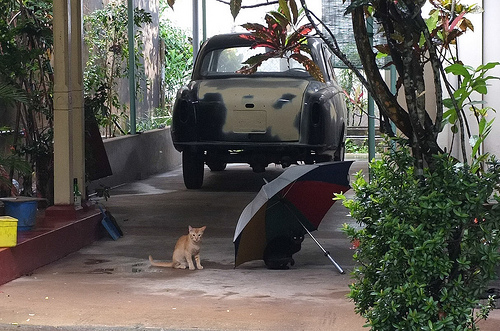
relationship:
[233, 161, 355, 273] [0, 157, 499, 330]
umbrella on top of ground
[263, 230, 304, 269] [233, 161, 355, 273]
cat underneath umbrella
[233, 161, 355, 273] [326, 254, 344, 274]
umbrella has handle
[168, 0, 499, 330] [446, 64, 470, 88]
plant has leaf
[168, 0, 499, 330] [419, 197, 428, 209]
plant has leaf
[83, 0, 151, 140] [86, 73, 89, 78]
plant has leaf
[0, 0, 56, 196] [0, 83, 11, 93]
plant has leaf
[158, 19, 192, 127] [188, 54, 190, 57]
plant has leaf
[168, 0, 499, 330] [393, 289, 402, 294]
plant has leaf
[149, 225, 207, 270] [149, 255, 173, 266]
cat has tail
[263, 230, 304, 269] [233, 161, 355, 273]
fire underneath umbrella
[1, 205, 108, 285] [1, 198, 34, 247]
ledge has buckets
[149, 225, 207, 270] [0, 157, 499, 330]
kitten on top of ground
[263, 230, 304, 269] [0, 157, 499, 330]
kitten on top of ground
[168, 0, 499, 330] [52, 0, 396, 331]
bush near carport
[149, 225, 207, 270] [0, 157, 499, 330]
cat on top of ground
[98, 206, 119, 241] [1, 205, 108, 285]
dustpan against ledge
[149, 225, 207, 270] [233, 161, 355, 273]
cat next to umbrella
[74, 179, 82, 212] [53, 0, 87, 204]
bottle next to post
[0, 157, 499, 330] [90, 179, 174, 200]
ground has moisture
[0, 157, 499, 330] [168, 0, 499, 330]
ground has bush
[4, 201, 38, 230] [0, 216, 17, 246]
planter next to container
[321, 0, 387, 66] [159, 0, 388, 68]
building in distance